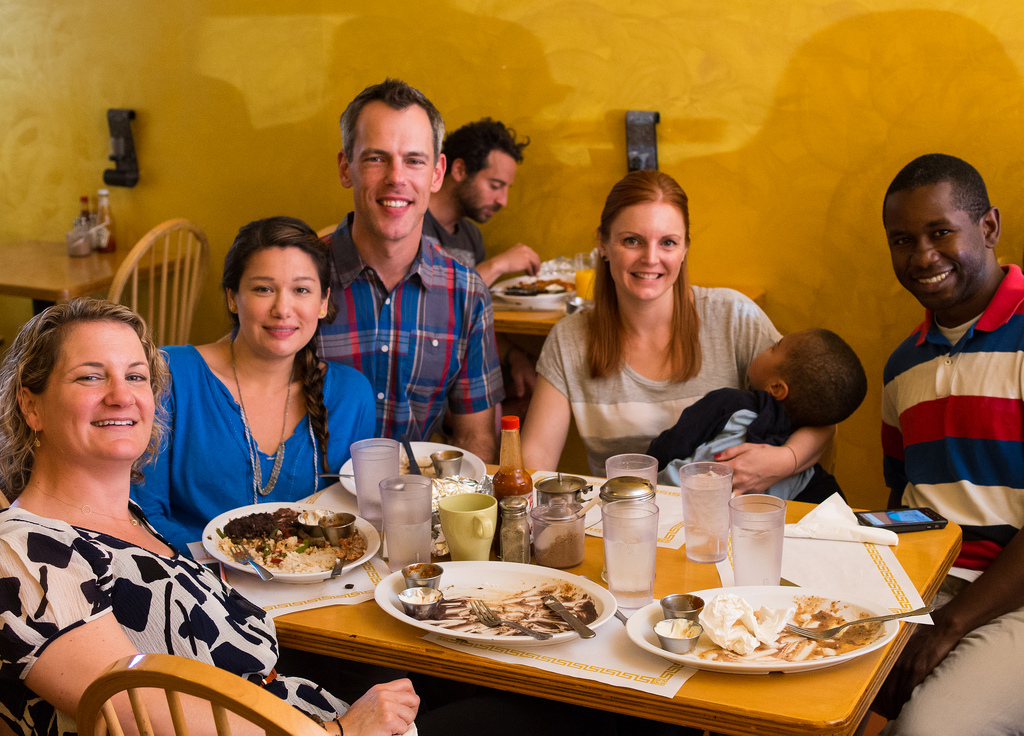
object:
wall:
[0, 0, 1024, 516]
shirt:
[881, 263, 1024, 583]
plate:
[375, 560, 619, 647]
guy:
[881, 153, 1024, 736]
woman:
[523, 169, 851, 504]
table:
[0, 241, 184, 318]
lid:
[499, 416, 519, 431]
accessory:
[102, 108, 140, 188]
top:
[202, 442, 949, 675]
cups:
[600, 453, 787, 609]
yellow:
[438, 494, 498, 562]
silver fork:
[469, 594, 597, 639]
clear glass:
[600, 499, 658, 609]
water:
[603, 536, 657, 608]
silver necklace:
[228, 337, 318, 503]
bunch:
[436, 493, 598, 569]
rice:
[206, 508, 367, 574]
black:
[852, 507, 947, 534]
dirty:
[397, 563, 599, 637]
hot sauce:
[493, 416, 534, 560]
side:
[169, 28, 334, 202]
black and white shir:
[536, 286, 785, 478]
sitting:
[128, 215, 375, 567]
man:
[217, 75, 505, 465]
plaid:
[403, 330, 463, 392]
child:
[644, 327, 868, 501]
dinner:
[202, 500, 938, 673]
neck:
[216, 331, 326, 367]